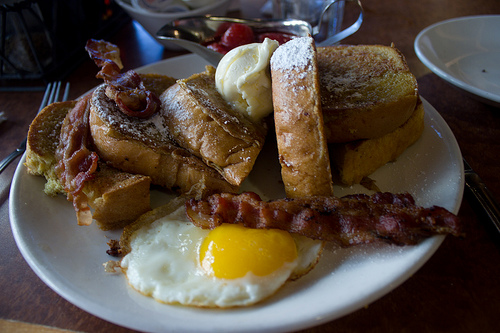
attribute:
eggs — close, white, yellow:
[113, 201, 303, 309]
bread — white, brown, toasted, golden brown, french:
[166, 31, 425, 191]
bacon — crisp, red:
[187, 188, 456, 249]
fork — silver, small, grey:
[1, 78, 75, 181]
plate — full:
[11, 38, 466, 330]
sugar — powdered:
[265, 30, 318, 79]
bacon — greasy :
[179, 171, 464, 245]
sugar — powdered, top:
[270, 32, 316, 95]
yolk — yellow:
[197, 223, 299, 277]